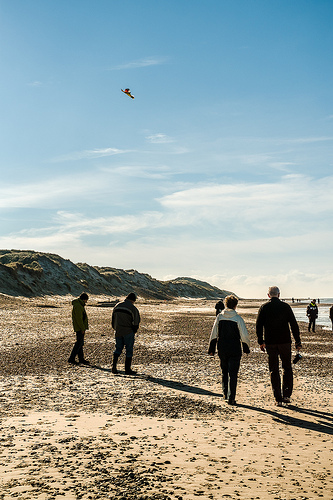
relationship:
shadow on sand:
[133, 369, 222, 405] [1, 312, 331, 499]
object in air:
[113, 83, 140, 104] [2, 1, 332, 260]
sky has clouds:
[3, 3, 331, 248] [4, 128, 329, 255]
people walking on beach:
[66, 282, 330, 413] [1, 312, 331, 499]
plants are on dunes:
[0, 245, 41, 257] [1, 249, 68, 299]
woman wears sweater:
[204, 292, 256, 408] [204, 310, 250, 358]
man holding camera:
[252, 283, 307, 407] [289, 351, 303, 368]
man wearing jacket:
[107, 293, 145, 376] [108, 299, 142, 337]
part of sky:
[5, 5, 53, 45] [3, 3, 331, 248]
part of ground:
[2, 444, 49, 498] [1, 312, 331, 499]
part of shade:
[191, 383, 213, 402] [133, 369, 222, 405]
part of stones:
[134, 473, 164, 497] [94, 461, 184, 499]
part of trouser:
[269, 377, 293, 394] [265, 340, 298, 409]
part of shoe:
[88, 359, 93, 369] [79, 356, 93, 370]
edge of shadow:
[234, 401, 261, 415] [234, 400, 332, 442]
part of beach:
[163, 315, 195, 331] [1, 312, 331, 499]